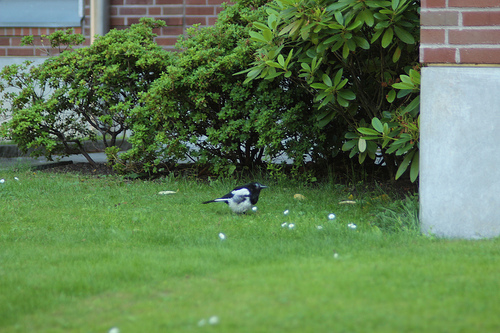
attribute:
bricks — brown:
[419, 0, 499, 65]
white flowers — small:
[216, 194, 345, 260]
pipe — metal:
[86, 3, 113, 45]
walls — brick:
[1, 4, 491, 70]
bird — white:
[202, 180, 269, 218]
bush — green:
[0, 11, 174, 175]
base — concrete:
[419, 65, 499, 238]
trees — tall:
[42, 19, 431, 193]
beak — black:
[258, 179, 268, 193]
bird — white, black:
[202, 179, 268, 214]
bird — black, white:
[200, 178, 270, 219]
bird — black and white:
[212, 161, 303, 258]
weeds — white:
[279, 204, 358, 259]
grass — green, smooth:
[0, 170, 500, 332]